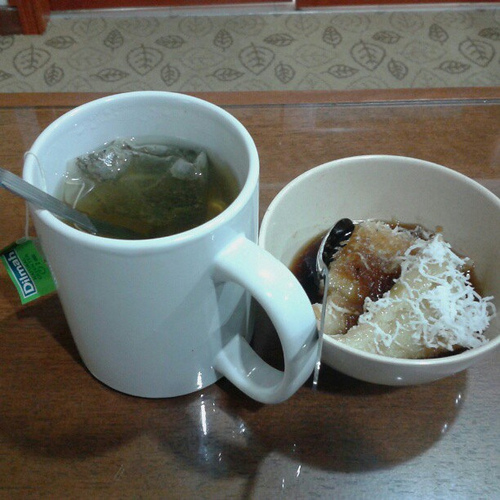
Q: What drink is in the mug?
A: Tea.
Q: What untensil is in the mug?
A: A spoon.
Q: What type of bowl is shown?
A: A small white bowl.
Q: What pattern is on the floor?
A: A leaf pattern.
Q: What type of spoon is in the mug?
A: A metal spoon.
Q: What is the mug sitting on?
A: A table.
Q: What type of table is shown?
A: A wood table.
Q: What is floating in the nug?
A: The tea bag.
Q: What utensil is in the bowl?
A: A spoon.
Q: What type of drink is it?
A: Tea.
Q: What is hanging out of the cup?
A: A teabag string.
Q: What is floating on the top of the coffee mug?
A: A tea bag.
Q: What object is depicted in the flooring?
A: Leaves.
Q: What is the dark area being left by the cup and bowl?
A: Shadow.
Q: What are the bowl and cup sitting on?
A: A table.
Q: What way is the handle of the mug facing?
A: To the right.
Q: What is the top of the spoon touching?
A: The handle of the cup.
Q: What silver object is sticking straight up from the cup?
A: A utensil.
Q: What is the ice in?
A: A mug.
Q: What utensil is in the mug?
A: Spoon.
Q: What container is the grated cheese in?
A: Bowl.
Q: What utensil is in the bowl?
A: Spoon.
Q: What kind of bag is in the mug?
A: Tea bag.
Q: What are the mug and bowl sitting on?
A: A wooden table.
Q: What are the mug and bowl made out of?
A: Ceramic.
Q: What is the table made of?
A: Wood.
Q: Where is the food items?
A: In the bowl.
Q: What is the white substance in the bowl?
A: Coconut.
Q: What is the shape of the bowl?
A: Round.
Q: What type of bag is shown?
A: Tea bag.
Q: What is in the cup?
A: Tea.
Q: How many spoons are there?
A: Two.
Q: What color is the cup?
A: White.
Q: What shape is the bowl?
A: Round.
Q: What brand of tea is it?
A: Dilmah.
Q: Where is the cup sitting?
A: On the table.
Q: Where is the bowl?
A: Next to the cup.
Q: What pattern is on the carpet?
A: Leaves.